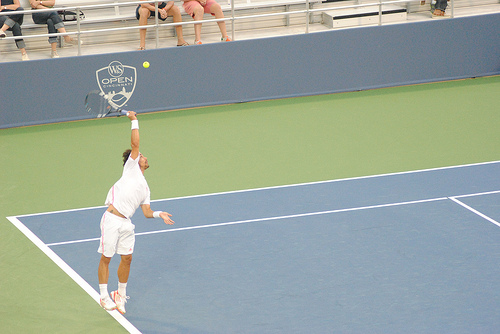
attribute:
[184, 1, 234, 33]
shorts — peach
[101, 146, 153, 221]
shirt — white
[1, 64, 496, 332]
court — green, blue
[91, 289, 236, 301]
shoes — red, white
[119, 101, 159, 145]
wristband — white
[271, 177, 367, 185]
line — white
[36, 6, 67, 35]
legs — crossed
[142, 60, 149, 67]
ball — yellow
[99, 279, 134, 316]
shoes — white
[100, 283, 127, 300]
socks — white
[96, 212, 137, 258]
shorts — white, black